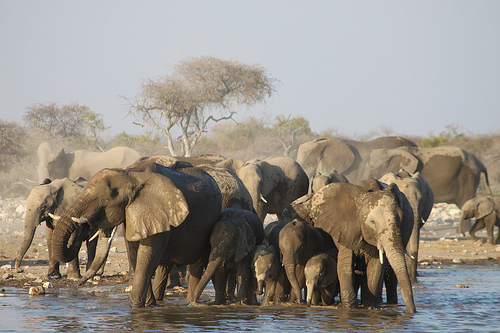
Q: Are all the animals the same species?
A: Yes, all the animals are elephants.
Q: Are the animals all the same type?
A: Yes, all the animals are elephants.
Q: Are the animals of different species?
A: No, all the animals are elephants.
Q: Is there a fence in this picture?
A: No, there are no fences.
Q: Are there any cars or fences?
A: No, there are no fences or cars.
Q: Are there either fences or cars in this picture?
A: No, there are no fences or cars.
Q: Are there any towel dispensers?
A: No, there are no towel dispensers.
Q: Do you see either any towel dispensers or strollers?
A: No, there are no towel dispensers or strollers.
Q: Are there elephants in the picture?
A: Yes, there are elephants.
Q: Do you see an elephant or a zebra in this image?
A: Yes, there are elephants.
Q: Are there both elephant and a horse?
A: No, there are elephants but no horses.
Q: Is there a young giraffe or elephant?
A: Yes, there are young elephants.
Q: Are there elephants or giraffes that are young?
A: Yes, the elephants are young.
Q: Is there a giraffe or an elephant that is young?
A: Yes, the elephants are young.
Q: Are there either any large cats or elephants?
A: Yes, there are large elephants.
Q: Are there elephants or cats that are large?
A: Yes, the elephants are large.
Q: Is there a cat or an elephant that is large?
A: Yes, the elephants are large.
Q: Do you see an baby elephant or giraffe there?
A: Yes, there are baby elephants.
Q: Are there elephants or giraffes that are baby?
A: Yes, the elephants are baby.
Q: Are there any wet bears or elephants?
A: Yes, there are wet elephants.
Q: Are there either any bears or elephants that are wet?
A: Yes, the elephants are wet.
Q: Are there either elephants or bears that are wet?
A: Yes, the elephants are wet.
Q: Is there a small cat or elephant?
A: Yes, there are small elephants.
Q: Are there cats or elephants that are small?
A: Yes, the elephants are small.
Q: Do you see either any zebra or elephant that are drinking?
A: Yes, the elephants are drinking.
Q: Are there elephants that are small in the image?
A: Yes, there are small elephants.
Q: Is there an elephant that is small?
A: Yes, there are elephants that are small.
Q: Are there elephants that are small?
A: Yes, there are elephants that are small.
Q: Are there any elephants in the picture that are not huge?
A: Yes, there are small elephants.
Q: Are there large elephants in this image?
A: Yes, there are large elephants.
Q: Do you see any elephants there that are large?
A: Yes, there are elephants that are large.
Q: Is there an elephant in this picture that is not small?
A: Yes, there are large elephants.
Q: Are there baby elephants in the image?
A: Yes, there are baby elephants.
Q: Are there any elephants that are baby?
A: Yes, there are elephants that are baby.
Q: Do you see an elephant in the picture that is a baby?
A: Yes, there are elephants that are baby.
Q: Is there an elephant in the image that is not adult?
A: Yes, there are baby elephants.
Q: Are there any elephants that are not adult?
A: Yes, there are baby elephants.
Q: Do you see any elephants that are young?
A: Yes, there are young elephants.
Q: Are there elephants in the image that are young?
A: Yes, there are elephants that are young.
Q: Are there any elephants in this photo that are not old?
A: Yes, there are young elephants.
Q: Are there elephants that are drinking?
A: Yes, there are elephants that are drinking.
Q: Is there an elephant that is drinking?
A: Yes, there are elephants that are drinking.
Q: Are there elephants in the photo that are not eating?
A: Yes, there are elephants that are drinking.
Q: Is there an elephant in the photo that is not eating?
A: Yes, there are elephants that are drinking.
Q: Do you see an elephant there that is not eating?
A: Yes, there are elephants that are drinking .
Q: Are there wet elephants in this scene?
A: Yes, there are wet elephants.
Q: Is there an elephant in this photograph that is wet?
A: Yes, there are elephants that are wet.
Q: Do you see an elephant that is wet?
A: Yes, there are elephants that are wet.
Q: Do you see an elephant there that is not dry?
A: Yes, there are wet elephants.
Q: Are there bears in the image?
A: No, there are no bears.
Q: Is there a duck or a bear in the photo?
A: No, there are no bears or ducks.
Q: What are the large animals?
A: The animals are elephants.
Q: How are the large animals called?
A: The animals are elephants.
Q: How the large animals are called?
A: The animals are elephants.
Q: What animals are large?
A: The animals are elephants.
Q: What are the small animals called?
A: The animals are elephants.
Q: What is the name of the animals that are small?
A: The animals are elephants.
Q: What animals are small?
A: The animals are elephants.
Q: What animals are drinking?
A: The animals are elephants.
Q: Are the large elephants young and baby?
A: Yes, the elephants are young and baby.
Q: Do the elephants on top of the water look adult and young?
A: No, the elephants are young but baby.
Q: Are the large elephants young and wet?
A: Yes, the elephants are young and wet.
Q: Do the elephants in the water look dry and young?
A: No, the elephants are young but wet.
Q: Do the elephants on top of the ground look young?
A: Yes, the elephants are young.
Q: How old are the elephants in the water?
A: The elephants are young.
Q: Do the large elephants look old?
A: No, the elephants are young.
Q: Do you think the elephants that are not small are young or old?
A: The elephants are young.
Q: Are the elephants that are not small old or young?
A: The elephants are young.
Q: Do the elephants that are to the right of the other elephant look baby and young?
A: Yes, the elephants are baby and young.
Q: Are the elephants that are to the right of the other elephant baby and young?
A: Yes, the elephants are baby and young.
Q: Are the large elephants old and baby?
A: No, the elephants are baby but young.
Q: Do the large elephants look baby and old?
A: No, the elephants are baby but young.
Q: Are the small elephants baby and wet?
A: Yes, the elephants are baby and wet.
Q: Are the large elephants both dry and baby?
A: No, the elephants are baby but wet.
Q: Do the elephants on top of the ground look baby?
A: Yes, the elephants are baby.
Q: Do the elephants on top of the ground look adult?
A: No, the elephants are baby.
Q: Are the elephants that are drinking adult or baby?
A: The elephants are baby.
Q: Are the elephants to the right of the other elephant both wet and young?
A: Yes, the elephants are wet and young.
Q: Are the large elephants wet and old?
A: No, the elephants are wet but young.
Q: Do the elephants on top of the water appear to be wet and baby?
A: Yes, the elephants are wet and baby.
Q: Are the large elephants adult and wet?
A: No, the elephants are wet but baby.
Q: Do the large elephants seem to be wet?
A: Yes, the elephants are wet.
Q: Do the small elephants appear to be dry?
A: No, the elephants are wet.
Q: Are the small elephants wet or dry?
A: The elephants are wet.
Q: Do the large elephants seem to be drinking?
A: Yes, the elephants are drinking.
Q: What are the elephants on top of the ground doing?
A: The elephants are drinking.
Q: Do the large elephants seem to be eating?
A: No, the elephants are drinking.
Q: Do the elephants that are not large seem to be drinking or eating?
A: The elephants are drinking.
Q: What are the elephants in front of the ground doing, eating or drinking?
A: The elephants are drinking.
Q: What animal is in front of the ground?
A: The elephants are in front of the ground.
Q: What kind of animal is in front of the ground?
A: The animals are elephants.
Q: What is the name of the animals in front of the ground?
A: The animals are elephants.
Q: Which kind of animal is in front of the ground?
A: The animals are elephants.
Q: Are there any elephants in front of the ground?
A: Yes, there are elephants in front of the ground.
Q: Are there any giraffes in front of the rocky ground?
A: No, there are elephants in front of the ground.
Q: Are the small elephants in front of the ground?
A: Yes, the elephants are in front of the ground.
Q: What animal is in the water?
A: The elephants are in the water.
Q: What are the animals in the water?
A: The animals are elephants.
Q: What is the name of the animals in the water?
A: The animals are elephants.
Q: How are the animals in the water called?
A: The animals are elephants.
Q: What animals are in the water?
A: The animals are elephants.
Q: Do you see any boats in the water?
A: No, there are elephants in the water.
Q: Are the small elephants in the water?
A: Yes, the elephants are in the water.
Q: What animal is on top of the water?
A: The elephants are on top of the water.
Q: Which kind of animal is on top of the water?
A: The animals are elephants.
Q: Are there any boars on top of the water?
A: No, there are elephants on top of the water.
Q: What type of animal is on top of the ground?
A: The animals are elephants.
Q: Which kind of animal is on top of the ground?
A: The animals are elephants.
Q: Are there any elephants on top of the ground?
A: Yes, there are elephants on top of the ground.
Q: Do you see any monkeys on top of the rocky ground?
A: No, there are elephants on top of the ground.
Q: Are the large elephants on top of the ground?
A: Yes, the elephants are on top of the ground.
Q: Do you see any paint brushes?
A: No, there are no paint brushes.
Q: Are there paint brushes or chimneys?
A: No, there are no paint brushes or chimneys.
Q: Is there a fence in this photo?
A: No, there are no fences.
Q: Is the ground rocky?
A: Yes, the ground is rocky.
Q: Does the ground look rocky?
A: Yes, the ground is rocky.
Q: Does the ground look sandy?
A: No, the ground is rocky.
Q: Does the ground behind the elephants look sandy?
A: No, the ground is rocky.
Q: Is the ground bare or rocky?
A: The ground is rocky.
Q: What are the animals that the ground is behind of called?
A: The animals are elephants.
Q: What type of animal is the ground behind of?
A: The ground is behind the elephants.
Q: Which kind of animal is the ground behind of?
A: The ground is behind the elephants.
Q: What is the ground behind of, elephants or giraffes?
A: The ground is behind elephants.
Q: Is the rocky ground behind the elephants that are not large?
A: Yes, the ground is behind the elephants.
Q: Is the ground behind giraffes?
A: No, the ground is behind the elephants.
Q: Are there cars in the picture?
A: No, there are no cars.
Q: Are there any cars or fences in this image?
A: No, there are no cars or fences.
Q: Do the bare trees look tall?
A: Yes, the trees are tall.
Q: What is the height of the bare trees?
A: The trees are tall.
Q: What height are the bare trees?
A: The trees are tall.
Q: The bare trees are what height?
A: The trees are tall.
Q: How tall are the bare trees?
A: The trees are tall.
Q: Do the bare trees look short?
A: No, the trees are tall.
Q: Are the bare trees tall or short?
A: The trees are tall.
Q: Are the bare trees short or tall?
A: The trees are tall.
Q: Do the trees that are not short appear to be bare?
A: Yes, the trees are bare.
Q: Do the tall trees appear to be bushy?
A: No, the trees are bare.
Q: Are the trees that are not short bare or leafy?
A: The trees are bare.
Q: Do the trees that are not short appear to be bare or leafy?
A: The trees are bare.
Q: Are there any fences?
A: No, there are no fences.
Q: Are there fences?
A: No, there are no fences.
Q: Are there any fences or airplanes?
A: No, there are no fences or airplanes.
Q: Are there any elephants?
A: Yes, there is an elephant.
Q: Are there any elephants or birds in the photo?
A: Yes, there is an elephant.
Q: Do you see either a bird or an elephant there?
A: Yes, there is an elephant.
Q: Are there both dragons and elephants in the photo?
A: No, there is an elephant but no dragons.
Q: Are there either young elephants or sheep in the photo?
A: Yes, there is a young elephant.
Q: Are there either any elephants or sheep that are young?
A: Yes, the elephant is young.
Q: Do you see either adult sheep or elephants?
A: Yes, there is an adult elephant.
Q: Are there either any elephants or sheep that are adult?
A: Yes, the elephant is adult.